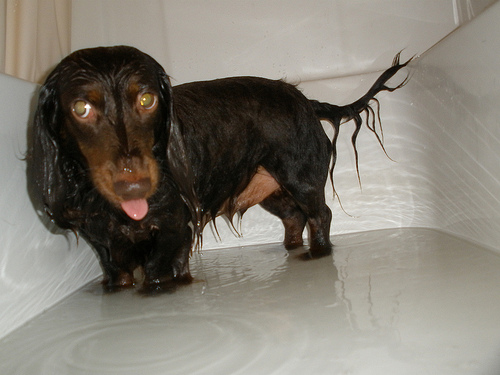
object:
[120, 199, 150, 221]
tongue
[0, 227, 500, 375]
water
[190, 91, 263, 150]
hair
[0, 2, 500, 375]
tub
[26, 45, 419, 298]
dog